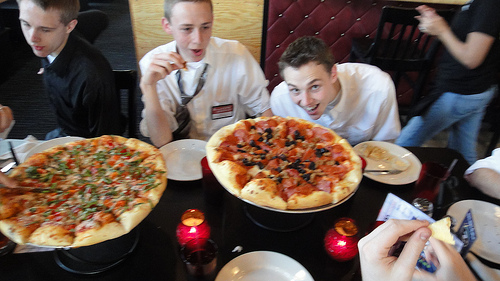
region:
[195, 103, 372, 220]
Pizza on top of black pan.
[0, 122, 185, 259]
A pizza covered in toppings.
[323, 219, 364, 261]
A candle on a table.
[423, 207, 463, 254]
food in a hand.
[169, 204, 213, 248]
A candle on a table.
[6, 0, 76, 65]
a man's head.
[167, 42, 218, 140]
a neck tie on a man.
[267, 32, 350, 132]
a man with a short hair cut.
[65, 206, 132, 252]
a crust on a pizza.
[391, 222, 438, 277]
a finger on a human hand.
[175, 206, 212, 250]
Candle on the dinner table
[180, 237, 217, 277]
Water glass on the dinner table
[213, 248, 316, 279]
Empty plate on the dinner table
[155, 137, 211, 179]
Round white dinner plate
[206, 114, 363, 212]
Pizza with black olive topping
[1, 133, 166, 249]
Pizza with green pepper topping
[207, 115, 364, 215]
Pizza with pepperoni topping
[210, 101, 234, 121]
Name tag on dress shirt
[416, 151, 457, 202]
Drinking glass on dinner table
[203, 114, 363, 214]
Freshly baked pizza on stand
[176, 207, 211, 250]
red glass candle holder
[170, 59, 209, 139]
grey striped neck tie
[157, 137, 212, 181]
small clean white dinner plate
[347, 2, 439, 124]
black painted bar stool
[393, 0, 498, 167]
server wearing a black apron and shirt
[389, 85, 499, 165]
blue denim jeans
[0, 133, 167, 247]
pizza with red and green toppings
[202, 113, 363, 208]
pizza with meat and black olive toppings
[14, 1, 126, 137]
young man in a black shirt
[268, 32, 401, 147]
young man in a white shirt leaning down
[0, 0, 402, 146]
group of boys at a pizzeria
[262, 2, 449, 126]
red quilted wall behind the boys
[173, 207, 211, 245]
lit red candle on the table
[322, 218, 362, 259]
lit red candle on the table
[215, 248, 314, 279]
empty clean white plate between the candles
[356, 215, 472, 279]
two hands holding a bit of crust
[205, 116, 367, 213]
hot fresh pizza with black olives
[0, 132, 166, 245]
thick crust pizza with green herbs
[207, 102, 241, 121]
rectangular red, white and black name tag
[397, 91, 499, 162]
blue jeans on a person walking by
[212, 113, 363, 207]
the pizza on the table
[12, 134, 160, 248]
the pizza on the table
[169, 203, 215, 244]
the candle on the table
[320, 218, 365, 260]
the candle on the table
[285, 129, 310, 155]
the olives on the pizza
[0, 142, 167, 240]
the pizza is sliced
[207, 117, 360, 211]
the pizza is sliced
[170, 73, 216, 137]
the boy wearing the striped tie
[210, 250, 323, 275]
the white plate on the table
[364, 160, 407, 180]
the utensil on the plate